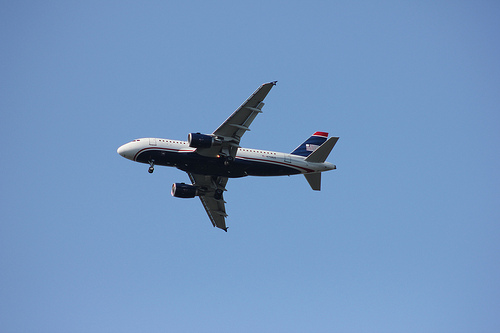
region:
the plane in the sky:
[115, 80, 337, 230]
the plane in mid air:
[117, 80, 338, 230]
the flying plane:
[117, 80, 339, 232]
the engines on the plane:
[170, 131, 221, 199]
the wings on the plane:
[185, 80, 277, 231]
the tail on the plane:
[290, 130, 332, 155]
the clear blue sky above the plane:
[0, 0, 499, 332]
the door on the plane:
[148, 138, 156, 145]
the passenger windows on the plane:
[158, 138, 276, 155]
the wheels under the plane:
[146, 165, 154, 173]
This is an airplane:
[89, 61, 364, 250]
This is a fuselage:
[121, 130, 315, 188]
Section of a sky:
[11, 76, 91, 241]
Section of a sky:
[166, 247, 323, 317]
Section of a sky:
[401, 198, 476, 320]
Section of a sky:
[398, 42, 493, 208]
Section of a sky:
[238, 20, 423, 72]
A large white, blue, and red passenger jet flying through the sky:
[117, 80, 340, 231]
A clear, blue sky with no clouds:
[1, 1, 499, 331]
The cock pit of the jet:
[128, 139, 145, 146]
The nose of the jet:
[118, 142, 130, 157]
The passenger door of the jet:
[148, 137, 156, 146]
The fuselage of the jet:
[141, 137, 335, 176]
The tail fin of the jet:
[292, 130, 328, 156]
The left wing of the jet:
[205, 79, 277, 148]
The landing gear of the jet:
[147, 156, 156, 173]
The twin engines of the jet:
[171, 130, 222, 197]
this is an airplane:
[20, 30, 461, 286]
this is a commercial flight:
[103, 105, 348, 205]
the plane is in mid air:
[27, 13, 358, 283]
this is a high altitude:
[50, 51, 406, 303]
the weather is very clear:
[38, 38, 431, 276]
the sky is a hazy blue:
[30, 34, 178, 159]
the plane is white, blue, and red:
[63, 88, 365, 252]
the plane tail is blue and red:
[298, 128, 328, 152]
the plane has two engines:
[144, 115, 219, 232]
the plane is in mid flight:
[95, 68, 392, 281]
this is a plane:
[73, 44, 368, 247]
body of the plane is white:
[118, 102, 343, 202]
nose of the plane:
[115, 137, 134, 159]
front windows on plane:
[123, 130, 150, 147]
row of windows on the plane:
[143, 137, 297, 168]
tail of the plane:
[283, 120, 336, 159]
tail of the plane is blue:
[289, 128, 330, 158]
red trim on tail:
[307, 115, 338, 142]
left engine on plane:
[185, 118, 221, 170]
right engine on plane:
[165, 176, 217, 213]